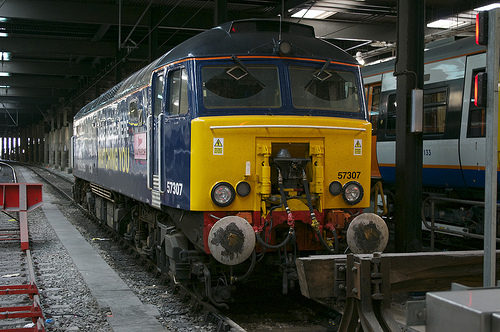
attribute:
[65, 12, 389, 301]
train engine — blue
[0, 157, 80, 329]
track — blocked off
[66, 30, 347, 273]
train — red, yellow, blue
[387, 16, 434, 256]
post — dark colored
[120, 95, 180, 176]
train — red, yellow, blue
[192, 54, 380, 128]
windshield — dusty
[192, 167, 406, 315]
bumper — round, metal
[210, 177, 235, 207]
lights — red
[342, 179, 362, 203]
lights — red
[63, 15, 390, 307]
train — blue, red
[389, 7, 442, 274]
beam — dark, metal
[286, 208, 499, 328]
barrier — metal, wood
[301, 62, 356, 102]
window — dirty 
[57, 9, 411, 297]
train — being repaired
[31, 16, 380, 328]
train — blue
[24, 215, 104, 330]
rocks — small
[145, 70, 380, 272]
train — blue, yellow, red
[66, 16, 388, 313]
blue train — yellow, red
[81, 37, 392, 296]
train — blue